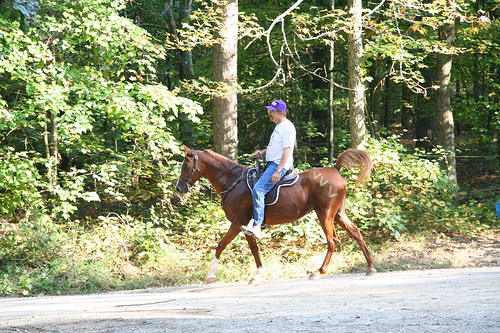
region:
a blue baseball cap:
[265, 95, 287, 109]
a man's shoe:
[243, 226, 265, 238]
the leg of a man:
[253, 163, 285, 230]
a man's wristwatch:
[276, 168, 283, 175]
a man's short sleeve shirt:
[263, 118, 296, 165]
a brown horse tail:
[333, 144, 373, 192]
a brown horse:
[175, 149, 385, 282]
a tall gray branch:
[214, 4, 245, 156]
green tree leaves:
[351, 143, 483, 233]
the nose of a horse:
[174, 185, 184, 192]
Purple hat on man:
[253, 88, 298, 122]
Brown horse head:
[163, 132, 240, 216]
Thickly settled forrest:
[19, 13, 157, 283]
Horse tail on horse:
[312, 138, 392, 293]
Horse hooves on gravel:
[187, 242, 403, 297]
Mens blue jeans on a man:
[238, 151, 291, 243]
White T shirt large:
[253, 115, 296, 186]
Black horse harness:
[170, 137, 210, 218]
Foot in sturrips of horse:
[230, 206, 265, 248]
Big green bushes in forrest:
[11, 183, 159, 293]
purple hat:
[266, 98, 288, 113]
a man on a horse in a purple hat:
[173, 96, 390, 281]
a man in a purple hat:
[241, 90, 299, 241]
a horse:
[166, 141, 386, 286]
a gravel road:
[12, 264, 499, 331]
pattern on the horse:
[303, 165, 340, 203]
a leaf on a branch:
[428, 84, 446, 93]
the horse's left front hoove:
[198, 270, 220, 287]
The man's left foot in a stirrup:
[238, 220, 271, 244]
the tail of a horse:
[337, 142, 382, 200]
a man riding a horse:
[175, 81, 395, 280]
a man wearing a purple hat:
[248, 90, 302, 133]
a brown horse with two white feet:
[150, 145, 402, 288]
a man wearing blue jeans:
[247, 94, 301, 243]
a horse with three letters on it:
[300, 151, 352, 214]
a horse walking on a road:
[123, 105, 460, 307]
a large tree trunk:
[201, 2, 251, 148]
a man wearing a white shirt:
[266, 93, 301, 183]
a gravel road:
[190, 290, 471, 330]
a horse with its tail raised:
[291, 137, 399, 220]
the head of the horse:
[176, 149, 204, 199]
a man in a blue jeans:
[251, 159, 283, 244]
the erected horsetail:
[335, 146, 372, 183]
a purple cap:
[265, 97, 287, 112]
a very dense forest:
[3, 44, 169, 211]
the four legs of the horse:
[205, 232, 375, 293]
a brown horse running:
[171, 148, 374, 278]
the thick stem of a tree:
[208, 40, 240, 146]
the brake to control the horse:
[173, 170, 203, 193]